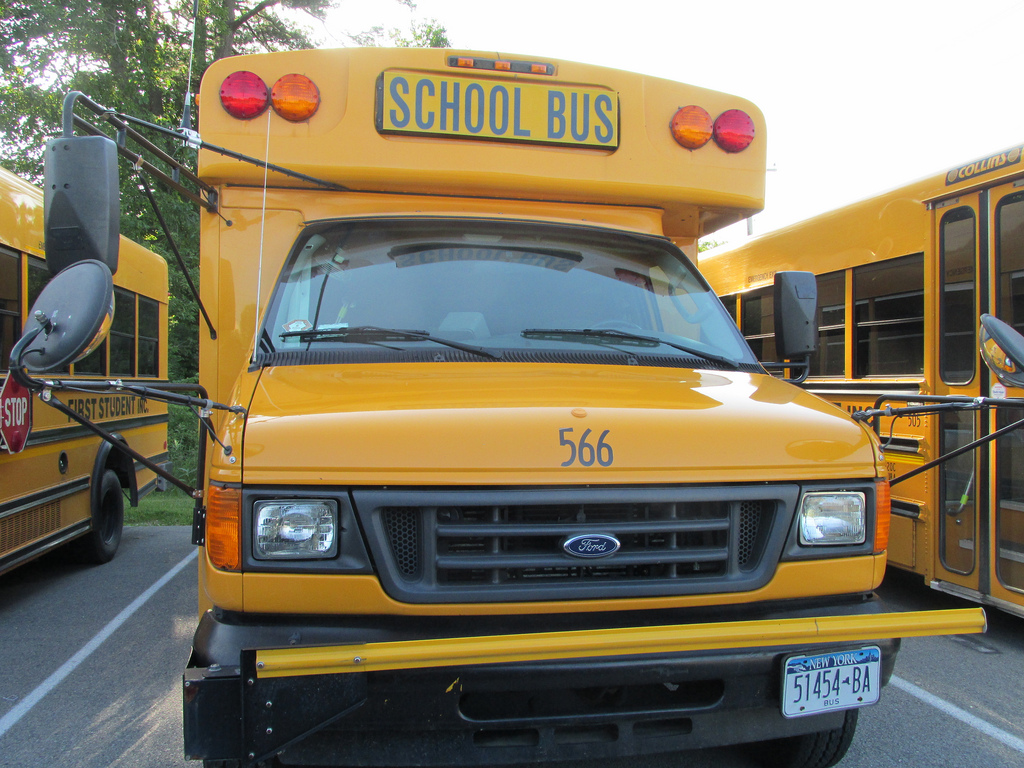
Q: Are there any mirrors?
A: Yes, there is a mirror.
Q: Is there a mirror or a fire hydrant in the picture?
A: Yes, there is a mirror.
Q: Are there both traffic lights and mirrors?
A: No, there is a mirror but no traffic lights.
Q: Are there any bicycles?
A: No, there are no bicycles.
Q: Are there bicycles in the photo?
A: No, there are no bicycles.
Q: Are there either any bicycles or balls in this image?
A: No, there are no bicycles or balls.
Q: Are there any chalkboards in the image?
A: No, there are no chalkboards.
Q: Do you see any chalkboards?
A: No, there are no chalkboards.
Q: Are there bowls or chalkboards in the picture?
A: No, there are no chalkboards or bowls.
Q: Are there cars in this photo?
A: No, there are no cars.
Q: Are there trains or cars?
A: No, there are no cars or trains.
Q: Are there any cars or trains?
A: No, there are no cars or trains.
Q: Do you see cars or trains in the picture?
A: No, there are no cars or trains.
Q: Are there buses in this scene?
A: Yes, there is a bus.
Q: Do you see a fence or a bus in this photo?
A: Yes, there is a bus.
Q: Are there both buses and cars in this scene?
A: No, there is a bus but no cars.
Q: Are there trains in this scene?
A: No, there are no trains.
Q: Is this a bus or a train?
A: This is a bus.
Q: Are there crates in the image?
A: No, there are no crates.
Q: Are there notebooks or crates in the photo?
A: No, there are no crates or notebooks.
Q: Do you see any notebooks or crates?
A: No, there are no crates or notebooks.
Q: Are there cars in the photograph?
A: No, there are no cars.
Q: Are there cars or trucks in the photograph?
A: No, there are no cars or trucks.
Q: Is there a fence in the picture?
A: No, there are no fences.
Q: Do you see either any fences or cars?
A: No, there are no fences or cars.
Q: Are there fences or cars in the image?
A: No, there are no fences or cars.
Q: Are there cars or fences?
A: No, there are no fences or cars.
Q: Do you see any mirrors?
A: Yes, there is a mirror.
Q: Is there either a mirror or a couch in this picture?
A: Yes, there is a mirror.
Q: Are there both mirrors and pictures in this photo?
A: No, there is a mirror but no pictures.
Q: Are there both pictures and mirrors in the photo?
A: No, there is a mirror but no pictures.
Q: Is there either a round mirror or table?
A: Yes, there is a round mirror.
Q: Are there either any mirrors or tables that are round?
A: Yes, the mirror is round.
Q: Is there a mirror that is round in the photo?
A: Yes, there is a round mirror.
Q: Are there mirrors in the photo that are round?
A: Yes, there is a mirror that is round.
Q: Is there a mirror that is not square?
A: Yes, there is a round mirror.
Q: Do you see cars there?
A: No, there are no cars.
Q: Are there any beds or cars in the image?
A: No, there are no cars or beds.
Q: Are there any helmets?
A: No, there are no helmets.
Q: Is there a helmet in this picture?
A: No, there are no helmets.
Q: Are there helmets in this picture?
A: No, there are no helmets.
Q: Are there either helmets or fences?
A: No, there are no helmets or fences.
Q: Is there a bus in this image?
A: Yes, there is a bus.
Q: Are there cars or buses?
A: Yes, there is a bus.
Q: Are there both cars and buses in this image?
A: No, there is a bus but no cars.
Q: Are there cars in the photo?
A: No, there are no cars.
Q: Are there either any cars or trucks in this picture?
A: No, there are no cars or trucks.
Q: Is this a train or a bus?
A: This is a bus.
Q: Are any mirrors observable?
A: Yes, there is a mirror.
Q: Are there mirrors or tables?
A: Yes, there is a mirror.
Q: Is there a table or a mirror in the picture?
A: Yes, there is a mirror.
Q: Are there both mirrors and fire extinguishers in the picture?
A: No, there is a mirror but no fire extinguishers.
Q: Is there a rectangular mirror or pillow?
A: Yes, there is a rectangular mirror.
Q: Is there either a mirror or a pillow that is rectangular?
A: Yes, the mirror is rectangular.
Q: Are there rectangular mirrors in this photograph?
A: Yes, there is a rectangular mirror.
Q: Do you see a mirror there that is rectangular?
A: Yes, there is a mirror that is rectangular.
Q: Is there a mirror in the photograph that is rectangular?
A: Yes, there is a mirror that is rectangular.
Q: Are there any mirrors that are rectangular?
A: Yes, there is a mirror that is rectangular.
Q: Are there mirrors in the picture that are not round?
A: Yes, there is a rectangular mirror.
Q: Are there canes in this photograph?
A: No, there are no canes.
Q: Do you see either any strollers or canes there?
A: No, there are no canes or strollers.